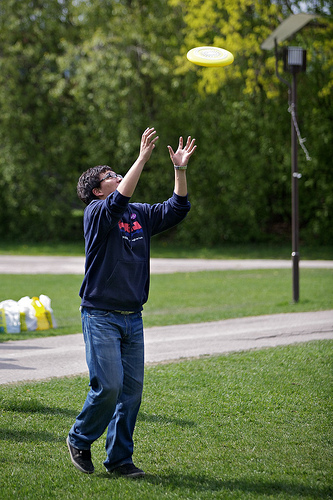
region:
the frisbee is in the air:
[185, 39, 240, 76]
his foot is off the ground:
[59, 431, 101, 480]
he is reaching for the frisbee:
[132, 28, 238, 181]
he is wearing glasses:
[102, 167, 124, 183]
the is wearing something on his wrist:
[169, 158, 191, 173]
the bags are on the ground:
[4, 300, 60, 332]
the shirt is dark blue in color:
[107, 257, 134, 281]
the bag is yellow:
[36, 306, 45, 324]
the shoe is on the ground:
[109, 458, 148, 485]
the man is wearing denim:
[70, 309, 145, 456]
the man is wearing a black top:
[81, 188, 185, 312]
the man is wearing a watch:
[173, 162, 188, 170]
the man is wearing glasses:
[96, 175, 121, 185]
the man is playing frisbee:
[185, 48, 235, 65]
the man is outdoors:
[3, 2, 332, 497]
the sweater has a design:
[114, 208, 138, 244]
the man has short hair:
[78, 163, 109, 197]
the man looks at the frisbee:
[190, 36, 243, 69]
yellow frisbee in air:
[183, 44, 235, 70]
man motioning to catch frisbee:
[63, 122, 199, 480]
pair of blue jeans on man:
[65, 303, 146, 474]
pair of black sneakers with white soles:
[61, 432, 145, 482]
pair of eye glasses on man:
[89, 168, 124, 189]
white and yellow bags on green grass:
[1, 291, 57, 339]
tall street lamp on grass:
[257, 9, 318, 303]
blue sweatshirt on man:
[77, 186, 193, 316]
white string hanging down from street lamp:
[286, 101, 313, 164]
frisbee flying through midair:
[184, 43, 236, 68]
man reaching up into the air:
[68, 124, 200, 478]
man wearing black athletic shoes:
[63, 434, 148, 479]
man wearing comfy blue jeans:
[66, 301, 145, 471]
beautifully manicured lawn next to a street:
[2, 338, 332, 498]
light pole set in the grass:
[259, 11, 322, 304]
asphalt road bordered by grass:
[0, 308, 332, 386]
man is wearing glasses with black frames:
[94, 169, 123, 187]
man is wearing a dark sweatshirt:
[77, 191, 192, 311]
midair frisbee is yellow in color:
[185, 45, 234, 68]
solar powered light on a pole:
[259, 7, 317, 308]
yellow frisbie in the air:
[183, 43, 238, 72]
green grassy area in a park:
[0, 341, 329, 497]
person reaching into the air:
[66, 127, 194, 481]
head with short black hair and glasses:
[76, 163, 122, 202]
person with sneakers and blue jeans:
[65, 299, 147, 488]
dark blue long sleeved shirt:
[80, 185, 196, 318]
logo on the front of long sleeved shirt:
[114, 208, 146, 250]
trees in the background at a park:
[0, 3, 331, 257]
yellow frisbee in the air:
[178, 41, 240, 78]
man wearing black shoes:
[64, 440, 142, 484]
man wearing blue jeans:
[73, 302, 138, 464]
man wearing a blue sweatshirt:
[79, 192, 198, 302]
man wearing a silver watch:
[170, 160, 191, 173]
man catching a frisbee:
[62, 104, 202, 483]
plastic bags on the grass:
[2, 287, 62, 340]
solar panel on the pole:
[258, 10, 311, 56]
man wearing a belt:
[106, 308, 136, 318]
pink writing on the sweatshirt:
[112, 219, 143, 238]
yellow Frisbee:
[176, 35, 245, 84]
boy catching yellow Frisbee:
[54, 98, 188, 472]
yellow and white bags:
[1, 289, 53, 337]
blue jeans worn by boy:
[78, 304, 150, 454]